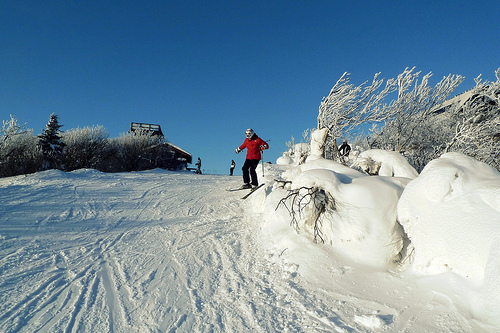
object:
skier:
[226, 122, 273, 198]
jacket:
[240, 137, 272, 160]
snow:
[1, 169, 498, 332]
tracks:
[2, 220, 144, 331]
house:
[405, 85, 500, 151]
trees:
[319, 67, 391, 156]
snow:
[332, 79, 355, 106]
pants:
[242, 157, 259, 190]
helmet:
[245, 129, 253, 137]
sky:
[0, 0, 499, 125]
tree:
[41, 108, 65, 164]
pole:
[260, 147, 270, 180]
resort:
[123, 118, 198, 172]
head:
[243, 127, 256, 140]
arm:
[259, 137, 269, 152]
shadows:
[0, 164, 172, 234]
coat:
[237, 131, 268, 163]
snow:
[69, 128, 163, 164]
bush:
[65, 142, 162, 168]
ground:
[4, 173, 272, 325]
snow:
[39, 110, 54, 139]